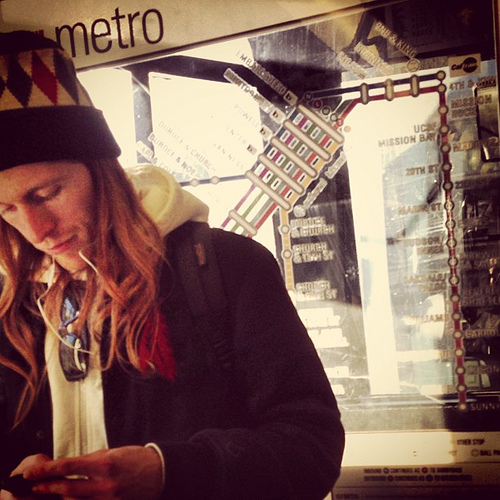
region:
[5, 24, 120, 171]
knitted cap with red and black diamonds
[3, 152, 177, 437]
man with long red wavy hair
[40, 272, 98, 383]
dark sunglasses held on front of shirt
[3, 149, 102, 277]
man with long face looking down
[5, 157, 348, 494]
white sweatshirt under black jacket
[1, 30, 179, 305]
a man wearing a hat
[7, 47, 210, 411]
a man with long hair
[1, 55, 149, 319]
a man with blonde hair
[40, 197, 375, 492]
black and white jacket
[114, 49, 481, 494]
mirror behind man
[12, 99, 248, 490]
man looking down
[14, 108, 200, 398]
man with short mustache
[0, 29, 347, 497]
man looking at cell phone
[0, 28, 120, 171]
knit cap on head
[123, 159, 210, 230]
white hood on back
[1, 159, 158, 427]
long red hair on chest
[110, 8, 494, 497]
map of bus routes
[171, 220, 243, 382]
strap on man's shoulder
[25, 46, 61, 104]
red diamond on hat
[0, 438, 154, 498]
cell phone in two hands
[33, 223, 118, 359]
white wires hanging from ears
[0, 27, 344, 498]
person is on phone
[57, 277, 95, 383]
the sunglasses are black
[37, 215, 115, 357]
white headphone cords in front of glasses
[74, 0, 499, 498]
Metro Map behind person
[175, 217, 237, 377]
strap to back pack on shoulder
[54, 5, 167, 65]
word METRO above person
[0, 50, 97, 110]
red and black diamonds on hat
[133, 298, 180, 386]
red feathers hanging from hair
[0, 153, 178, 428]
person has long hair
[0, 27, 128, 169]
man with a ski hat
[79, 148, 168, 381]
man with long red hair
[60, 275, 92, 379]
man with sunglasses on hoodie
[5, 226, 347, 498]
black jacket on hippie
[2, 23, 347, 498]
man is looking at his phone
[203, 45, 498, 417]
rail line map behind the man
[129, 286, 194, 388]
red feather in mans hair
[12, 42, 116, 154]
knitted beanie with triangles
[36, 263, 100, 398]
sunglasses folded and hung on shirt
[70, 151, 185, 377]
man's long brown hair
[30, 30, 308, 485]
man in a beanie and black jacket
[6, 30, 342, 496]
man in the subway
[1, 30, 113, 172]
patterned hat on the man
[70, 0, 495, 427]
map of the subway in the background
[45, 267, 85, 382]
sunglasses on the mans hoodie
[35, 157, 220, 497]
white colored hoodie on the man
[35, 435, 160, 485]
left hand of the man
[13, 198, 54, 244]
nose of the man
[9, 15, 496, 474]
this is a train station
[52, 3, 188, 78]
the text is black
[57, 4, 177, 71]
the text says METRO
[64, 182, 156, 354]
the hair is red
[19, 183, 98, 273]
this is the man's face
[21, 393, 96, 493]
the man is texting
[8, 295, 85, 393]
these are sunglasses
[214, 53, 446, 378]
this is a train map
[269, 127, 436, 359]
the map is reflective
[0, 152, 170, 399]
the man has long hair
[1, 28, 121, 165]
the man is wearing a hat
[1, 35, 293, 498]
the man is looking down at his phone